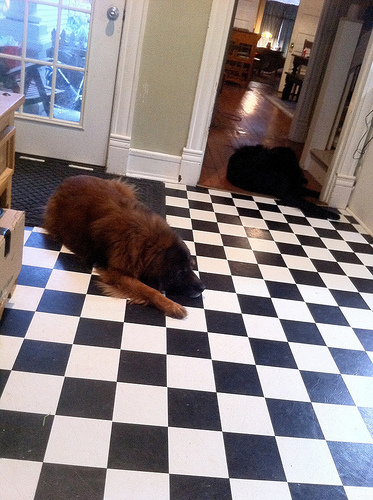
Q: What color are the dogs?
A: Brown.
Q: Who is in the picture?
A: 2 dogs.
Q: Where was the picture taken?
A: In a house.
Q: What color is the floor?
A: Black and white.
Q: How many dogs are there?
A: 2.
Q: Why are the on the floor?
A: Sleeping.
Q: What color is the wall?
A: Beige.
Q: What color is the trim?
A: White.